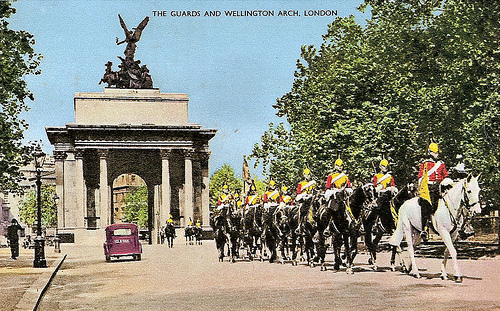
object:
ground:
[0, 245, 498, 309]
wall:
[75, 92, 190, 124]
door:
[112, 170, 147, 238]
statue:
[97, 14, 160, 92]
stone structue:
[42, 87, 216, 251]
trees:
[398, 0, 500, 223]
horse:
[382, 167, 485, 284]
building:
[44, 12, 220, 260]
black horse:
[319, 178, 380, 271]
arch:
[108, 165, 155, 242]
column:
[97, 149, 110, 230]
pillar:
[181, 147, 196, 228]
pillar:
[158, 148, 173, 226]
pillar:
[73, 148, 86, 226]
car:
[103, 223, 143, 263]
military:
[210, 138, 482, 283]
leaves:
[331, 22, 356, 37]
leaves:
[0, 43, 29, 70]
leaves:
[1, 143, 36, 163]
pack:
[210, 141, 485, 280]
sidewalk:
[0, 243, 64, 310]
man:
[5, 217, 24, 260]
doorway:
[44, 122, 223, 245]